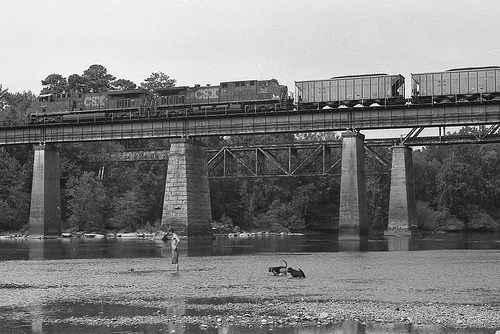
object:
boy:
[168, 227, 182, 274]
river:
[0, 230, 500, 262]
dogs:
[268, 260, 288, 277]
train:
[23, 66, 500, 124]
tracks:
[18, 97, 500, 124]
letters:
[83, 96, 93, 107]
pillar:
[159, 140, 217, 244]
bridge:
[0, 93, 500, 248]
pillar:
[28, 141, 62, 240]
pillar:
[336, 133, 369, 242]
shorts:
[171, 249, 179, 265]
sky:
[0, 0, 500, 95]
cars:
[407, 66, 500, 104]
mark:
[159, 218, 190, 240]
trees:
[135, 70, 177, 90]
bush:
[65, 170, 107, 230]